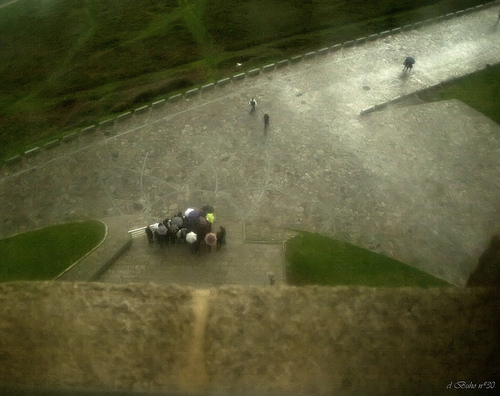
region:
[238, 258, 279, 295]
edge of a wall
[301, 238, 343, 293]
part of a grass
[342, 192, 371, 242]
part of a floor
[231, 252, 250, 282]
part of a floor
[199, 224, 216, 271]
part of an umbrella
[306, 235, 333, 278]
part of a grass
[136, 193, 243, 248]
group of people with umbrellas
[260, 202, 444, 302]
green grass patch on right of people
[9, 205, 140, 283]
green grass patch on left of people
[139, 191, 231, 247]
people standing on wet surface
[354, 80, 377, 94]
round man hole cover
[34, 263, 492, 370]
stone ledge in foreground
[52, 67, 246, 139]
edges on paved road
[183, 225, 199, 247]
white opened umrella in crowd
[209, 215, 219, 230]
green opened umrella in crowd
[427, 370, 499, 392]
photographer's name in lower corner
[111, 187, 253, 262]
group of people on the ground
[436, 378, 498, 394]
name in bottom right corner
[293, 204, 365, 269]
gray and green ground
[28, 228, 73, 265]
grass next to people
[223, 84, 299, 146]
two people walking together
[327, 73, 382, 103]
light hitting the ground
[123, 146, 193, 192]
lines on the ground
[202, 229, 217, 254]
one umbrella in the photo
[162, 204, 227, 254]
many umbrellas in the photo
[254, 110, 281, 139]
one person on the cement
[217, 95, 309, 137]
two people on the ground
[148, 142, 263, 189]
lines on the ground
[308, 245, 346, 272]
grass next to the people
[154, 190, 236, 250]
people grouped together with each other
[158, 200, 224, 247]
umbrellas above the people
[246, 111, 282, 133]
one person on the ground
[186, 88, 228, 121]
white line on the ground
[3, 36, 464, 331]
many people on the ground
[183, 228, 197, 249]
white umbrella in the photo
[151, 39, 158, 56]
patch of green grass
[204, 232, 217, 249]
umbrella covering a person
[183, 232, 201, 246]
umbrella covering a person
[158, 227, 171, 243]
umbrella covering a person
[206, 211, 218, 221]
umbrella covering a person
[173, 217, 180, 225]
umbrella covering a person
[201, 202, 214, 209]
umbrella covering a person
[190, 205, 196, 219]
umbrella covering a person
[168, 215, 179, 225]
umbrella covering a person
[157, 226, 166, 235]
umbrella covering a person